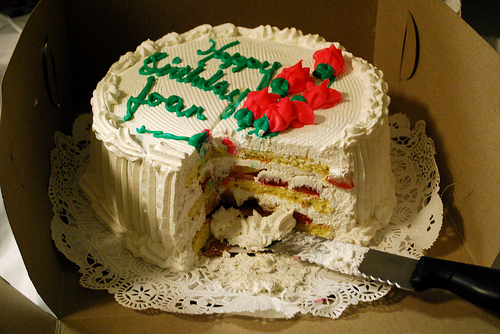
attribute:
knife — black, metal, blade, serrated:
[272, 225, 499, 328]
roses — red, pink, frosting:
[244, 33, 352, 159]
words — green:
[130, 34, 283, 167]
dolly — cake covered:
[368, 118, 456, 275]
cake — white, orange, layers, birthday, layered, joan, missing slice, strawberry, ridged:
[79, 18, 401, 283]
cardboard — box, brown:
[9, 7, 492, 330]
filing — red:
[226, 171, 330, 240]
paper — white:
[39, 111, 174, 320]